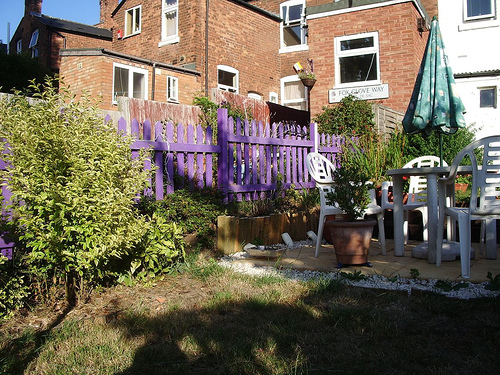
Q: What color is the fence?
A: Purple.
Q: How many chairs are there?
A: Three.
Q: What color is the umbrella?
A: Green.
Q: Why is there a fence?
A: Enclosure.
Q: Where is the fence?
A: Against the wall.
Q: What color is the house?
A: Brick.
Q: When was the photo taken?
A: Afternoon.